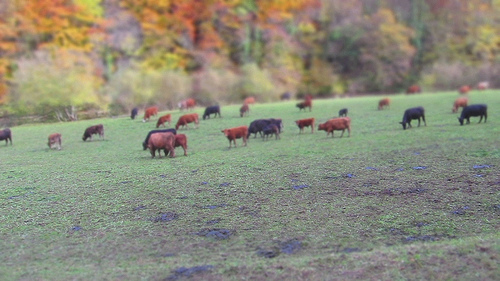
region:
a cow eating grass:
[0, 125, 16, 147]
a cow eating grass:
[38, 128, 67, 154]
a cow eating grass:
[75, 121, 106, 146]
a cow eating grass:
[397, 103, 431, 137]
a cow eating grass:
[142, 133, 178, 159]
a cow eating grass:
[231, 93, 261, 116]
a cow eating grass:
[172, 110, 202, 127]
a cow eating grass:
[201, 103, 222, 118]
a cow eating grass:
[138, 106, 160, 121]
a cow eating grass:
[372, 91, 392, 113]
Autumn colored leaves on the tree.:
[2, 0, 309, 100]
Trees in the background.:
[2, 0, 498, 129]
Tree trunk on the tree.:
[46, 102, 80, 125]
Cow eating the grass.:
[455, 101, 493, 128]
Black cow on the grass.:
[397, 104, 432, 131]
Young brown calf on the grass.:
[220, 123, 252, 147]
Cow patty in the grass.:
[197, 221, 236, 243]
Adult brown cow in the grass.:
[145, 130, 177, 158]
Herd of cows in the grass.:
[0, 78, 498, 159]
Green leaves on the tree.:
[412, 16, 430, 58]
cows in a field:
[44, 8, 499, 239]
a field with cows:
[75, 62, 490, 268]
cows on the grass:
[89, 71, 376, 267]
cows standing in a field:
[40, 73, 499, 279]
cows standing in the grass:
[12, 63, 322, 276]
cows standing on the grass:
[65, 25, 425, 269]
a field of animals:
[82, 53, 489, 192]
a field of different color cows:
[46, 15, 499, 194]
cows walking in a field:
[75, 57, 482, 260]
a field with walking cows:
[47, 68, 465, 211]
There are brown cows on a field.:
[291, 113, 372, 139]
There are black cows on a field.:
[388, 100, 486, 134]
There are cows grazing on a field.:
[33, 122, 119, 154]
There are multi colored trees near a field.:
[10, 13, 262, 82]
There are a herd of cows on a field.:
[126, 104, 355, 165]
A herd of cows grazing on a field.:
[107, 111, 322, 158]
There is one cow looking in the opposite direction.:
[207, 122, 255, 148]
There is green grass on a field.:
[196, 182, 380, 273]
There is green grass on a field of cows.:
[108, 178, 195, 243]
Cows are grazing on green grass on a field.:
[381, 92, 484, 139]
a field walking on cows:
[79, 88, 464, 254]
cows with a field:
[91, 83, 425, 278]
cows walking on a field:
[85, 61, 497, 240]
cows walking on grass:
[74, 28, 490, 238]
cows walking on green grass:
[49, 32, 360, 262]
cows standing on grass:
[100, 36, 411, 263]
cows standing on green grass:
[53, 94, 450, 278]